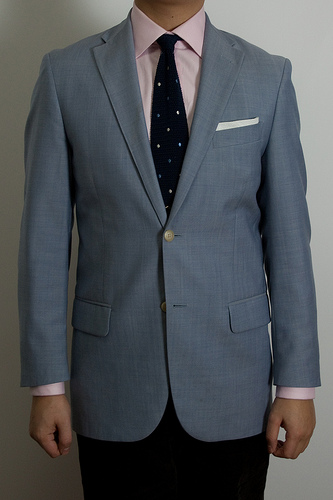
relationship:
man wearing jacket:
[15, 0, 320, 497] [16, 3, 322, 444]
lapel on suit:
[91, 28, 175, 238] [12, 23, 322, 444]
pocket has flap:
[224, 289, 271, 371] [226, 291, 270, 335]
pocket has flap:
[68, 300, 114, 367] [71, 296, 112, 338]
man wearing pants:
[17, 0, 322, 500] [78, 395, 274, 497]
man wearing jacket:
[17, 0, 322, 500] [15, 11, 320, 387]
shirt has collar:
[129, 1, 207, 143] [131, 4, 205, 57]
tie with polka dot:
[150, 30, 190, 217] [157, 81, 161, 87]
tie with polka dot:
[150, 30, 190, 217] [157, 113, 161, 117]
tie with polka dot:
[150, 30, 190, 217] [175, 110, 181, 114]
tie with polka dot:
[150, 30, 190, 217] [164, 126, 171, 130]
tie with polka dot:
[150, 30, 190, 217] [155, 143, 161, 147]